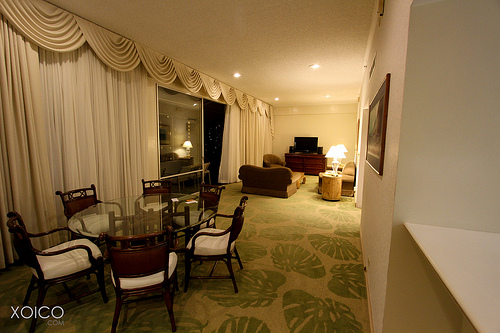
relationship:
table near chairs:
[62, 188, 223, 252] [6, 200, 203, 327]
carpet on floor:
[253, 196, 362, 331] [248, 197, 363, 329]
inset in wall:
[429, 38, 480, 331] [359, 7, 404, 311]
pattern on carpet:
[258, 223, 339, 330] [253, 196, 362, 331]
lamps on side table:
[321, 139, 348, 175] [307, 167, 344, 204]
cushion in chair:
[43, 239, 105, 281] [0, 205, 111, 321]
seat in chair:
[113, 247, 181, 288] [92, 219, 190, 327]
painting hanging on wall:
[357, 65, 390, 178] [357, 35, 403, 313]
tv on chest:
[291, 135, 320, 153] [283, 151, 326, 180]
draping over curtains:
[224, 89, 274, 127] [182, 75, 283, 198]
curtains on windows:
[16, 49, 160, 229] [159, 84, 203, 188]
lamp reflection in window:
[180, 136, 202, 161] [158, 90, 203, 200]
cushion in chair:
[30, 229, 107, 279] [0, 205, 111, 321]